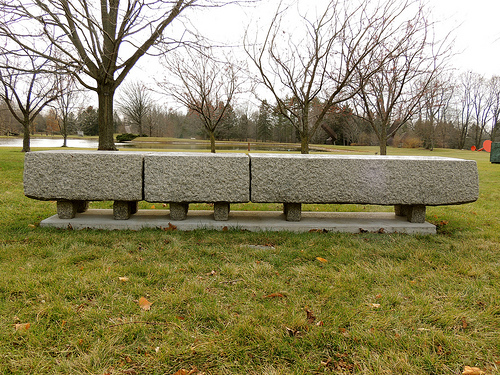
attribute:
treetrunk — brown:
[91, 88, 114, 152]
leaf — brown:
[264, 287, 293, 301]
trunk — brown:
[68, 91, 152, 153]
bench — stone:
[20, 151, 479, 223]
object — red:
[483, 137, 495, 154]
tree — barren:
[251, 27, 378, 129]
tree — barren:
[347, 24, 442, 151]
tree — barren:
[176, 62, 232, 146]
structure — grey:
[282, 166, 342, 199]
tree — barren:
[52, 0, 184, 146]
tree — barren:
[156, 48, 246, 151]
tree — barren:
[239, 0, 371, 155]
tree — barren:
[346, 17, 433, 154]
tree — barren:
[121, 83, 151, 135]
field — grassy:
[1, 132, 496, 373]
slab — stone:
[341, 209, 447, 237]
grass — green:
[125, 257, 422, 364]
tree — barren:
[124, 85, 220, 132]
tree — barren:
[440, 67, 492, 149]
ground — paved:
[4, 139, 100, 151]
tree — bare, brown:
[31, 7, 153, 168]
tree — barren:
[153, 39, 260, 150]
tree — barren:
[330, 32, 432, 160]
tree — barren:
[239, 12, 370, 162]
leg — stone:
[272, 177, 314, 229]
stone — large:
[19, 148, 499, 206]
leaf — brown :
[135, 295, 153, 310]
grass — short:
[109, 281, 242, 345]